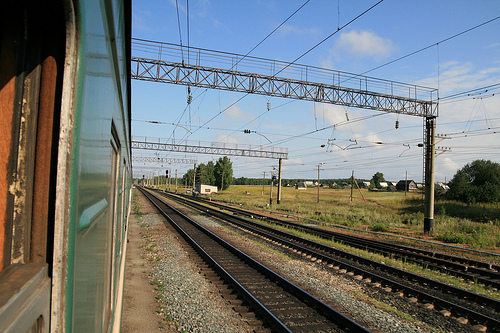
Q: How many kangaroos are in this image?
A: Zero.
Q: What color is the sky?
A: Blue.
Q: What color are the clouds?
A: White.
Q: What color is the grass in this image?
A: Green.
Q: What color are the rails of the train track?
A: Black.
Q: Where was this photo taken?
A: Train tracks.